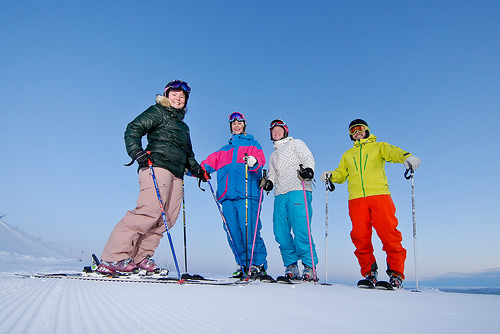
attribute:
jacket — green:
[108, 91, 203, 184]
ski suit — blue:
[183, 133, 273, 283]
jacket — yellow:
[328, 140, 405, 202]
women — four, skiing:
[87, 60, 441, 297]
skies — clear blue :
[23, 30, 419, 61]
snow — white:
[32, 295, 271, 318]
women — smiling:
[68, 55, 428, 323]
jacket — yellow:
[318, 135, 423, 200]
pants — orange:
[338, 190, 408, 269]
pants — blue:
[274, 195, 314, 265]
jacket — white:
[261, 141, 311, 194]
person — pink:
[198, 104, 269, 279]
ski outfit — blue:
[202, 138, 272, 273]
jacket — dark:
[109, 102, 201, 178]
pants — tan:
[102, 159, 198, 299]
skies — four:
[55, 254, 432, 307]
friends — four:
[94, 73, 432, 283]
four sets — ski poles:
[145, 154, 420, 294]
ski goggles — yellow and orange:
[346, 120, 366, 133]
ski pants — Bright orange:
[345, 194, 409, 279]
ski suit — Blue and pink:
[195, 133, 267, 272]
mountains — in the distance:
[426, 261, 472, 290]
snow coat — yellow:
[320, 138, 410, 204]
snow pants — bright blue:
[271, 191, 321, 273]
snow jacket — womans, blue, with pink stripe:
[196, 130, 270, 202]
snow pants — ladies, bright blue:
[267, 190, 319, 275]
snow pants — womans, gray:
[101, 167, 188, 270]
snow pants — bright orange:
[345, 198, 410, 278]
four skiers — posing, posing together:
[86, 72, 421, 292]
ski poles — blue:
[406, 187, 418, 292]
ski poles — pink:
[388, 203, 434, 296]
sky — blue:
[318, 24, 424, 94]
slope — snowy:
[8, 193, 64, 280]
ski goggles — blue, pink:
[226, 109, 242, 130]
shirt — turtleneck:
[277, 139, 305, 185]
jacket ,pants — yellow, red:
[230, 139, 253, 282]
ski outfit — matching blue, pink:
[217, 140, 254, 278]